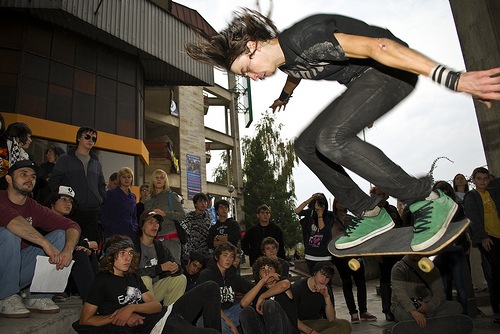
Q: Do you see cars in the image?
A: No, there are no cars.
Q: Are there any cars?
A: No, there are no cars.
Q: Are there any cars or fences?
A: No, there are no cars or fences.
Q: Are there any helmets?
A: No, there are no helmets.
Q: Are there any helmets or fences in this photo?
A: No, there are no helmets or fences.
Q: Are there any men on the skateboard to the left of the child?
A: Yes, there is a man on the skateboard.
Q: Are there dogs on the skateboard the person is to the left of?
A: No, there is a man on the skateboard.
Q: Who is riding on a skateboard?
A: The man is riding on a skateboard.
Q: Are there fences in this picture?
A: No, there are no fences.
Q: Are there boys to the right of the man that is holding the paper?
A: Yes, there are boys to the right of the man.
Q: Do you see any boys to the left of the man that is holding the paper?
A: No, the boys are to the right of the man.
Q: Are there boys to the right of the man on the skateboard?
A: Yes, there are boys to the right of the man.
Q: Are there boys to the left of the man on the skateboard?
A: No, the boys are to the right of the man.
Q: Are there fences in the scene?
A: No, there are no fences.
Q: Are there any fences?
A: No, there are no fences.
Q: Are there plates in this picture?
A: No, there are no plates.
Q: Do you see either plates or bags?
A: No, there are no plates or bags.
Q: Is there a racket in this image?
A: No, there are no rackets.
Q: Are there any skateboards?
A: Yes, there is a skateboard.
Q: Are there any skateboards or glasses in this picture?
A: Yes, there is a skateboard.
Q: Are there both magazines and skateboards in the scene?
A: No, there is a skateboard but no magazines.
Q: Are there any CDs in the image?
A: No, there are no cds.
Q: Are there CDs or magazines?
A: No, there are no CDs or magazines.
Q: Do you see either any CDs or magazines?
A: No, there are no CDs or magazines.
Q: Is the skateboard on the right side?
A: Yes, the skateboard is on the right of the image.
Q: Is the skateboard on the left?
A: No, the skateboard is on the right of the image.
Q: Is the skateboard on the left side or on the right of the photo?
A: The skateboard is on the right of the image.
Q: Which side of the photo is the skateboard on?
A: The skateboard is on the right of the image.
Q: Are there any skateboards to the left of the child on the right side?
A: Yes, there is a skateboard to the left of the child.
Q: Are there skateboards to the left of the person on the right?
A: Yes, there is a skateboard to the left of the child.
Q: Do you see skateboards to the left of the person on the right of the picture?
A: Yes, there is a skateboard to the left of the child.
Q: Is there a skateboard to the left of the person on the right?
A: Yes, there is a skateboard to the left of the child.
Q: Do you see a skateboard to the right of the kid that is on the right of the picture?
A: No, the skateboard is to the left of the kid.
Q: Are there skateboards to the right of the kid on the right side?
A: No, the skateboard is to the left of the kid.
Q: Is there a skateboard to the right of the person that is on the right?
A: No, the skateboard is to the left of the kid.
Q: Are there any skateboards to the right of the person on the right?
A: No, the skateboard is to the left of the kid.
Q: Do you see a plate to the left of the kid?
A: No, there is a skateboard to the left of the kid.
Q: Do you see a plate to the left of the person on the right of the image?
A: No, there is a skateboard to the left of the kid.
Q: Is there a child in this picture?
A: Yes, there is a child.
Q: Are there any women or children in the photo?
A: Yes, there is a child.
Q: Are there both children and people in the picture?
A: Yes, there are both a child and a person.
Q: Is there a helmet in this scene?
A: No, there are no helmets.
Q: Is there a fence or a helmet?
A: No, there are no helmets or fences.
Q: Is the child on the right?
A: Yes, the child is on the right of the image.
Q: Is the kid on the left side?
A: No, the kid is on the right of the image.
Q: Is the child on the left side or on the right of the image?
A: The child is on the right of the image.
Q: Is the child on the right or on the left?
A: The child is on the right of the image.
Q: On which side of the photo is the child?
A: The child is on the right of the image.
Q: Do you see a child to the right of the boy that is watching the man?
A: Yes, there is a child to the right of the boy.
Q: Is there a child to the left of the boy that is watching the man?
A: No, the child is to the right of the boy.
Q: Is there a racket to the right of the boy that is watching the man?
A: No, there is a child to the right of the boy.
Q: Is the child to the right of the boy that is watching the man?
A: Yes, the child is to the right of the boy.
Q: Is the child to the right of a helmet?
A: No, the child is to the right of the boy.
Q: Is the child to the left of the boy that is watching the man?
A: No, the child is to the right of the boy.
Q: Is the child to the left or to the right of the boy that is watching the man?
A: The child is to the right of the boy.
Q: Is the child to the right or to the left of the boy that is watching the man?
A: The child is to the right of the boy.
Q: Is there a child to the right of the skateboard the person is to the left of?
A: Yes, there is a child to the right of the skateboard.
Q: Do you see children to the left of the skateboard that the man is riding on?
A: No, the child is to the right of the skateboard.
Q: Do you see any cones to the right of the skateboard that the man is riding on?
A: No, there is a child to the right of the skateboard.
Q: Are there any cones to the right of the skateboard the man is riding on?
A: No, there is a child to the right of the skateboard.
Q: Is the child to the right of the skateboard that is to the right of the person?
A: Yes, the child is to the right of the skateboard.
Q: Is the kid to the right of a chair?
A: No, the kid is to the right of the skateboard.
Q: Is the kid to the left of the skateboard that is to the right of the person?
A: No, the kid is to the right of the skateboard.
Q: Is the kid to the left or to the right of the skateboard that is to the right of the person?
A: The kid is to the right of the skateboard.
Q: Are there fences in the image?
A: No, there are no fences.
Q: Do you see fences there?
A: No, there are no fences.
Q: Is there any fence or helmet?
A: No, there are no fences or helmets.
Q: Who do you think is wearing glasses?
A: The boy is wearing glasses.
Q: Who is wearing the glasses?
A: The boy is wearing glasses.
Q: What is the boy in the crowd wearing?
A: The boy is wearing glasses.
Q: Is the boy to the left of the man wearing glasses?
A: Yes, the boy is wearing glasses.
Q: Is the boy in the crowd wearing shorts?
A: No, the boy is wearing glasses.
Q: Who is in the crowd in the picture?
A: The boy is in the crowd.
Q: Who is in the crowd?
A: The boy is in the crowd.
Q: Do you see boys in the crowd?
A: Yes, there is a boy in the crowd.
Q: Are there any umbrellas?
A: No, there are no umbrellas.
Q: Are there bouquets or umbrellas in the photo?
A: No, there are no umbrellas or bouquets.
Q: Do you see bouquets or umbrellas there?
A: No, there are no umbrellas or bouquets.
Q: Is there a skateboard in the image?
A: Yes, there is a skateboard.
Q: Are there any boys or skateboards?
A: Yes, there is a skateboard.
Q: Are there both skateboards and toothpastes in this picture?
A: No, there is a skateboard but no toothpastes.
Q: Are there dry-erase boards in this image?
A: No, there are no dry-erase boards.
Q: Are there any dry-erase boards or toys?
A: No, there are no dry-erase boards or toys.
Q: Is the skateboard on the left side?
A: No, the skateboard is on the right of the image.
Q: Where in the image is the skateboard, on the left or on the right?
A: The skateboard is on the right of the image.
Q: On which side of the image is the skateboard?
A: The skateboard is on the right of the image.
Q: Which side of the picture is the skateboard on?
A: The skateboard is on the right of the image.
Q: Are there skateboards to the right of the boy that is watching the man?
A: Yes, there is a skateboard to the right of the boy.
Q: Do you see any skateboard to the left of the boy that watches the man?
A: No, the skateboard is to the right of the boy.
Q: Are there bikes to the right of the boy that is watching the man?
A: No, there is a skateboard to the right of the boy.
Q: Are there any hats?
A: Yes, there is a hat.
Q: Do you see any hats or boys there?
A: Yes, there is a hat.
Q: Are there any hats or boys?
A: Yes, there is a hat.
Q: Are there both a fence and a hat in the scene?
A: No, there is a hat but no fences.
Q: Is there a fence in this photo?
A: No, there are no fences.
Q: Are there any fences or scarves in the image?
A: No, there are no fences or scarves.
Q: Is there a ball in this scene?
A: No, there are no balls.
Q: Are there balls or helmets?
A: No, there are no balls or helmets.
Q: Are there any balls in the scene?
A: No, there are no balls.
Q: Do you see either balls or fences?
A: No, there are no balls or fences.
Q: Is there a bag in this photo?
A: No, there are no bags.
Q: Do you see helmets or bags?
A: No, there are no bags or helmets.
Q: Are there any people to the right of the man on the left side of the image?
A: Yes, there is a person to the right of the man.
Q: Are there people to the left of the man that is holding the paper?
A: No, the person is to the right of the man.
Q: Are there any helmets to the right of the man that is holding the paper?
A: No, there is a person to the right of the man.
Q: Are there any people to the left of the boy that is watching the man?
A: Yes, there is a person to the left of the boy.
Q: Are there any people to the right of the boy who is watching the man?
A: No, the person is to the left of the boy.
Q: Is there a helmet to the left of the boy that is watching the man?
A: No, there is a person to the left of the boy.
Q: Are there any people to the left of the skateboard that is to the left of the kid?
A: Yes, there is a person to the left of the skateboard.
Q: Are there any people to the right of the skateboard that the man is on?
A: No, the person is to the left of the skateboard.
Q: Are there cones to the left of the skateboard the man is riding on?
A: No, there is a person to the left of the skateboard.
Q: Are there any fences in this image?
A: No, there are no fences.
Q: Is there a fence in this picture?
A: No, there are no fences.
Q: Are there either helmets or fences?
A: No, there are no fences or helmets.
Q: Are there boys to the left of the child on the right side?
A: Yes, there is a boy to the left of the child.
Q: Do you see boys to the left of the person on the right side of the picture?
A: Yes, there is a boy to the left of the child.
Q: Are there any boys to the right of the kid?
A: No, the boy is to the left of the kid.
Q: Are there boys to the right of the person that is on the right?
A: No, the boy is to the left of the kid.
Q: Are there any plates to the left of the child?
A: No, there is a boy to the left of the child.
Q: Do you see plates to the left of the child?
A: No, there is a boy to the left of the child.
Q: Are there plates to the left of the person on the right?
A: No, there is a boy to the left of the child.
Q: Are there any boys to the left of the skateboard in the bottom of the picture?
A: Yes, there is a boy to the left of the skateboard.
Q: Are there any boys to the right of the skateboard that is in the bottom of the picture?
A: No, the boy is to the left of the skateboard.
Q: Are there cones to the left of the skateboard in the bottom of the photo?
A: No, there is a boy to the left of the skateboard.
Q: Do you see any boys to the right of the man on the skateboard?
A: Yes, there is a boy to the right of the man.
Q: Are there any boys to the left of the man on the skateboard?
A: No, the boy is to the right of the man.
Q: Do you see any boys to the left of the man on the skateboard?
A: No, the boy is to the right of the man.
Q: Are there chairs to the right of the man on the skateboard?
A: No, there is a boy to the right of the man.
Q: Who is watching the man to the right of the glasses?
A: The boy is watching the man.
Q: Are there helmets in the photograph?
A: No, there are no helmets.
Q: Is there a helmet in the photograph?
A: No, there are no helmets.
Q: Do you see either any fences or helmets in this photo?
A: No, there are no helmets or fences.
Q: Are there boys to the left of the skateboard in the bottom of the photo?
A: Yes, there is a boy to the left of the skateboard.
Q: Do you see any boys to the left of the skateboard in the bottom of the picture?
A: Yes, there is a boy to the left of the skateboard.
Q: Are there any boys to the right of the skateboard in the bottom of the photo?
A: No, the boy is to the left of the skateboard.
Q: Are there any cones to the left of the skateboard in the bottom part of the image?
A: No, there is a boy to the left of the skateboard.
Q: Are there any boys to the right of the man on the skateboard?
A: Yes, there is a boy to the right of the man.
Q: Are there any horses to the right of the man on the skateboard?
A: No, there is a boy to the right of the man.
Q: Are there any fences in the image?
A: No, there are no fences.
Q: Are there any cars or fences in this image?
A: No, there are no fences or cars.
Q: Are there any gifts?
A: No, there are no gifts.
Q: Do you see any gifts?
A: No, there are no gifts.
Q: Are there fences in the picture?
A: No, there are no fences.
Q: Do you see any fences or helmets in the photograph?
A: No, there are no fences or helmets.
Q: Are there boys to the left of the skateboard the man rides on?
A: Yes, there is a boy to the left of the skateboard.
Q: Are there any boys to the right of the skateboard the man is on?
A: No, the boy is to the left of the skateboard.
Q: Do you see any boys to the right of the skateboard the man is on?
A: No, the boy is to the left of the skateboard.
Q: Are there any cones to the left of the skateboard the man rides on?
A: No, there is a boy to the left of the skateboard.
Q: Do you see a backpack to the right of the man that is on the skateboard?
A: No, there is a boy to the right of the man.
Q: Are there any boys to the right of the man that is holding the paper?
A: Yes, there is a boy to the right of the man.